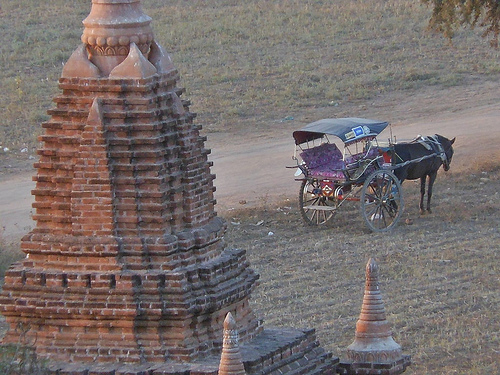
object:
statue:
[0, 0, 412, 375]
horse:
[387, 133, 456, 215]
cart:
[285, 117, 405, 235]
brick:
[82, 172, 98, 179]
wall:
[66, 97, 113, 240]